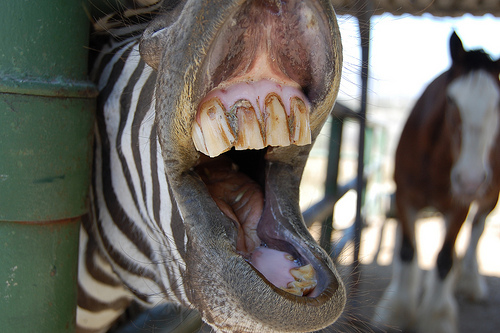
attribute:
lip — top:
[161, 0, 339, 115]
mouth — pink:
[157, 5, 356, 330]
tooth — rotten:
[226, 95, 267, 152]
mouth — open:
[157, 18, 372, 321]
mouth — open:
[171, 3, 347, 308]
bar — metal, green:
[0, 2, 107, 328]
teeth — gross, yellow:
[204, 106, 323, 158]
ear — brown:
[421, 29, 492, 74]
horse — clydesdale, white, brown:
[366, 24, 499, 331]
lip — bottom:
[188, 226, 376, 328]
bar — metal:
[357, 134, 365, 172]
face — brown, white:
[451, 64, 498, 217]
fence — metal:
[121, 176, 371, 331]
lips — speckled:
[152, 0, 345, 332]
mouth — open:
[174, 27, 313, 297]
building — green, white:
[3, 6, 90, 332]